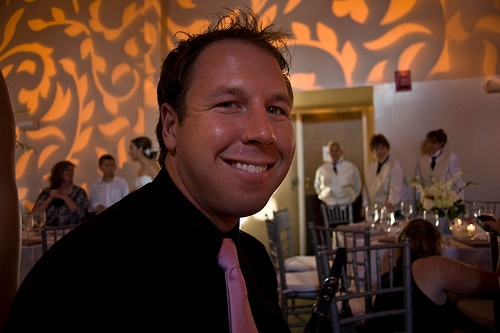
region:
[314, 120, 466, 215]
three members of wait staff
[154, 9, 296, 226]
smiling man with spikey hair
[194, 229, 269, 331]
pink tie on black shirt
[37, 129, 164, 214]
bride and two guests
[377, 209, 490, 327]
woman in sleeveless top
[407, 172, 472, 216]
flowers in center of table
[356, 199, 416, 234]
goblets full of water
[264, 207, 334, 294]
empty chairs facing table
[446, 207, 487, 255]
candles on white tablecloth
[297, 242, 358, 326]
purse strap on chair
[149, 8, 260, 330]
man smiling wearing pink tie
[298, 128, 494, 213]
server standing in the corner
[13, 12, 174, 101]
lighted decorations in the wall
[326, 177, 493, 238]
table with wine glass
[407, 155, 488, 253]
flower on top of the table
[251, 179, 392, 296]
silver painted chairs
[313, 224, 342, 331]
purse on the side of the chair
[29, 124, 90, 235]
lady standing talking to people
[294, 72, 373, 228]
door in the middle of the building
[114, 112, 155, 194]
lady with pink dress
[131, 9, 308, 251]
man smiling at camera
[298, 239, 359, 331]
Purse hung on chair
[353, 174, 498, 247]
flowers and glasses on table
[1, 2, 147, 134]
orange design on walls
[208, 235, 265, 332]
A pink tie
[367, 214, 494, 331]
woman sitting on the floor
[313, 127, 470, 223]
three servers against a wall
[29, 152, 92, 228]
woman in a black and white shirt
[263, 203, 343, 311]
two empty chairs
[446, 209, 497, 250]
candles lit on the table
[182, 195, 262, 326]
man is wearing pink tie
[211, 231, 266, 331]
pink tie around man's neck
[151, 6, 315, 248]
man with spiky haircut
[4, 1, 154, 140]
luminary wall paper on wall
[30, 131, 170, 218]
people talking to bride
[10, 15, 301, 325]
man smiling at camera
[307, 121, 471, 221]
three waiters standing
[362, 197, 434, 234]
wine goblets with water on table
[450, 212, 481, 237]
two candles on table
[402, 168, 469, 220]
white flower arrangement on table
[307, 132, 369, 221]
waiter in white vest